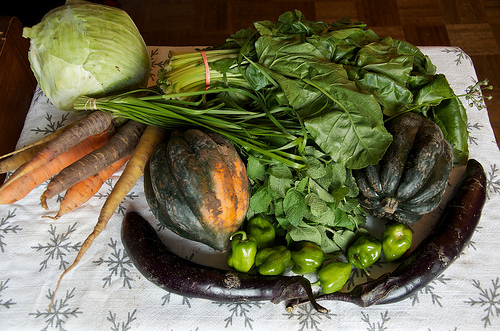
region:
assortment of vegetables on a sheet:
[10, 10, 488, 328]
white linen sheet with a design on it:
[0, 210, 70, 326]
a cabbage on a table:
[20, 0, 155, 101]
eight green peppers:
[230, 210, 405, 281]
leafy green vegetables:
[170, 25, 400, 126]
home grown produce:
[15, 5, 492, 317]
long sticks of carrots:
[11, 105, 121, 245]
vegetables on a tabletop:
[10, 2, 490, 302]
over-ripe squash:
[146, 130, 241, 225]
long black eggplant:
[121, 263, 311, 301]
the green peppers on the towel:
[226, 216, 415, 293]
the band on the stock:
[83, 97, 99, 110]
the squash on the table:
[357, 106, 452, 228]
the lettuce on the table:
[240, 7, 436, 92]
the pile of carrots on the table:
[1, 116, 158, 261]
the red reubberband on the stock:
[196, 48, 216, 92]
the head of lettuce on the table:
[21, 2, 155, 107]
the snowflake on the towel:
[23, 218, 83, 268]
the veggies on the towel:
[1, 5, 486, 330]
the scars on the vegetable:
[430, 243, 452, 265]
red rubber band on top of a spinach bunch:
[198, 50, 211, 90]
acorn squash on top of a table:
[146, 120, 248, 254]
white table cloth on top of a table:
[0, 46, 499, 329]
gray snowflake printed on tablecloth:
[28, 219, 85, 271]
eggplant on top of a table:
[121, 209, 335, 315]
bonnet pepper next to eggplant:
[228, 228, 255, 263]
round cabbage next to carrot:
[21, 3, 151, 111]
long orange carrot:
[45, 123, 154, 314]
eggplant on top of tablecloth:
[281, 158, 494, 308]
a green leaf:
[261, 58, 392, 171]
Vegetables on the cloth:
[1, 6, 495, 306]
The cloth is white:
[0, 33, 495, 323]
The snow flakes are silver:
[13, 29, 495, 326]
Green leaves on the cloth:
[70, 19, 467, 159]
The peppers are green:
[222, 219, 413, 297]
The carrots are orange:
[1, 87, 163, 303]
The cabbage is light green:
[21, 6, 155, 98]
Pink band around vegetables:
[193, 41, 217, 96]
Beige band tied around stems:
[81, 96, 102, 113]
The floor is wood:
[0, 4, 493, 151]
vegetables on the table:
[24, 15, 499, 320]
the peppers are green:
[222, 223, 345, 294]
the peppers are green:
[222, 199, 392, 310]